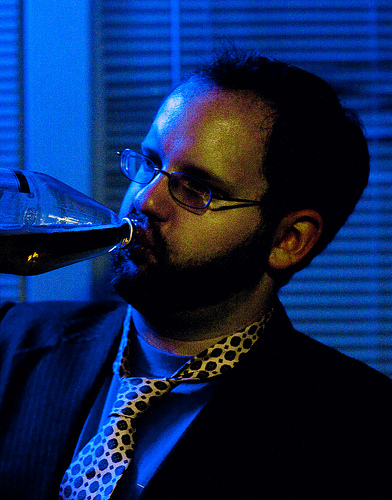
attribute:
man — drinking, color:
[0, 42, 372, 499]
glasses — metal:
[105, 146, 268, 219]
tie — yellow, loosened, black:
[42, 302, 279, 500]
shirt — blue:
[41, 332, 250, 499]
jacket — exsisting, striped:
[1, 279, 389, 499]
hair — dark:
[197, 54, 362, 278]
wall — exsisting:
[26, 3, 119, 306]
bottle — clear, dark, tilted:
[2, 167, 143, 279]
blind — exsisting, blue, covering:
[98, 9, 387, 383]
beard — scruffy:
[94, 219, 274, 312]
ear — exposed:
[266, 199, 324, 276]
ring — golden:
[114, 217, 134, 253]